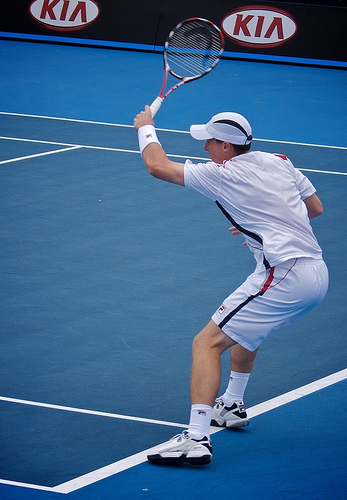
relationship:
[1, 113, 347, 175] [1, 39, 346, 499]
boundary line of court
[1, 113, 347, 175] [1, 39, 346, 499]
boundary line on court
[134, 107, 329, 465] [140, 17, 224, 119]
man holding racket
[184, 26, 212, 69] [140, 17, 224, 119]
logo on racket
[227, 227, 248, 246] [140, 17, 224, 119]
right hand without racket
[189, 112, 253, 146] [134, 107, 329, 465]
cap of player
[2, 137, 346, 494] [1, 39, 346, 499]
playable area of court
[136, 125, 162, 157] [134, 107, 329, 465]
wristband for man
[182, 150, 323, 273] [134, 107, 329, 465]
shirt on man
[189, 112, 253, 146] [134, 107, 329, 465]
hat on man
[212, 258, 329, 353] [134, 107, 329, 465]
shorts on man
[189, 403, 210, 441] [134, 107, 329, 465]
sock of man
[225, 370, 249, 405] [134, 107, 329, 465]
sock of man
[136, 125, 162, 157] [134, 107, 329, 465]
wristband of man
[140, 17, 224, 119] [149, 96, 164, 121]
racket has white handle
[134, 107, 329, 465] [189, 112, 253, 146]
man wearing cap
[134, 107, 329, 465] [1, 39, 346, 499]
man on court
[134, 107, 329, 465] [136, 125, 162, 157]
man wearing wristband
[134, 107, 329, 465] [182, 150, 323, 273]
man wearing shirt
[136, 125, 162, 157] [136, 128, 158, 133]
sleeve on wrist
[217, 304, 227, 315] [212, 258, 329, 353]
logo on shorts